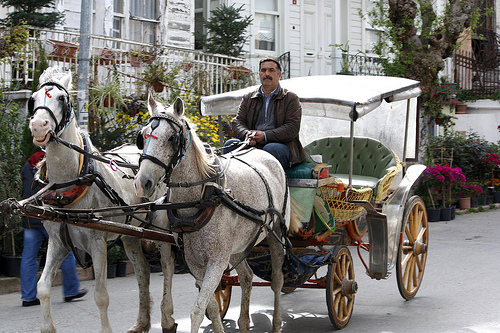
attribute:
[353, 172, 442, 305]
spokes — yellow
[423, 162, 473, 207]
flower — purple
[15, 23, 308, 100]
gate — iron, white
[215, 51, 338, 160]
man — wearing clothes, holding straps, wearing jacket, wearing jeans, on cart, sitting, driver, serious, wearing pants, shirted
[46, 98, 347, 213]
reins — black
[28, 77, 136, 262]
horse — wearing harness, pulling cart, white, harnessed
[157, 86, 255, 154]
flowers — yellow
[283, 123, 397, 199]
seat — green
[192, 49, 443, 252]
cart — on street, green, white, wheeled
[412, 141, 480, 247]
flowers — purple, red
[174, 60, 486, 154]
roof — white, canopy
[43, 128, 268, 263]
strap — black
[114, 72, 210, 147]
flower — yellow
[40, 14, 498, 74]
building — white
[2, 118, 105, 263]
person — walking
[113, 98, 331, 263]
horse — spotted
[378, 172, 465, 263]
wheel — orange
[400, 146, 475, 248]
vase — black, brown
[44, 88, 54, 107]
spot — red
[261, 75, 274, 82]
mustache — black